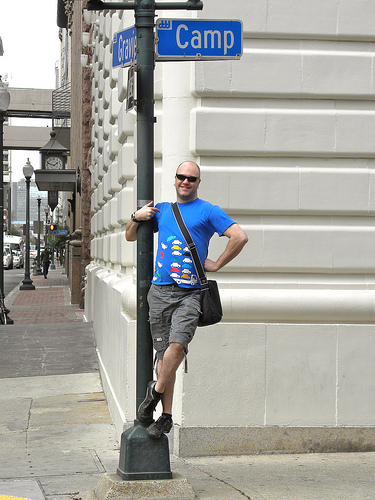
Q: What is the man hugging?
A: Pole.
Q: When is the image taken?
A: Hugging pole.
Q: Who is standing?
A: A man.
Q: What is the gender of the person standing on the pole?
A: Male.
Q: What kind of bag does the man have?
A: Shoulder bag.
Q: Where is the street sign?
A: On a corner.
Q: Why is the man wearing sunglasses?
A: To protect from the sun.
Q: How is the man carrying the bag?
A: On his shoulder.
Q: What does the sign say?
A: Camp.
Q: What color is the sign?
A: Blue.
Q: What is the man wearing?
A: Shorts.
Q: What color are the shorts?
A: Gray.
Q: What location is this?
A: The city.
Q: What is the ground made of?
A: Stone.